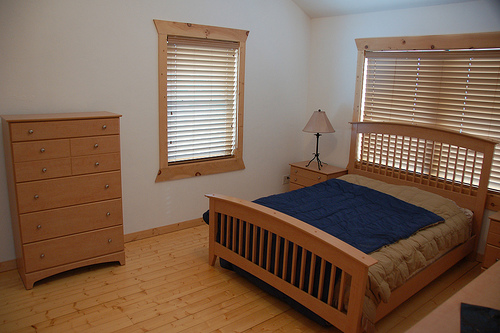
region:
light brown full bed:
[222, 133, 493, 301]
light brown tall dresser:
[16, 96, 139, 278]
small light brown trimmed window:
[150, 15, 247, 180]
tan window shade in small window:
[162, 35, 241, 157]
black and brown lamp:
[302, 103, 337, 180]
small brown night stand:
[271, 163, 350, 191]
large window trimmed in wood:
[350, 34, 496, 204]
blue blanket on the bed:
[232, 172, 442, 285]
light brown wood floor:
[145, 226, 207, 331]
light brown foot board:
[186, 188, 396, 317]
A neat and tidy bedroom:
[1, 1, 499, 331]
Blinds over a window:
[162, 32, 242, 165]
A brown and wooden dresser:
[2, 106, 132, 291]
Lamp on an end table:
[284, 103, 349, 194]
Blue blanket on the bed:
[196, 174, 448, 304]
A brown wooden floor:
[0, 222, 482, 331]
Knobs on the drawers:
[20, 119, 119, 264]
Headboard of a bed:
[343, 114, 498, 216]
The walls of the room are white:
[2, 0, 499, 264]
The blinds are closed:
[162, 31, 499, 198]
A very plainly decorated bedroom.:
[8, 12, 497, 324]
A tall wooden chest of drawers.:
[5, 103, 130, 285]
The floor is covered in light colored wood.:
[13, 175, 494, 331]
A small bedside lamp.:
[298, 98, 336, 172]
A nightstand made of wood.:
[280, 155, 343, 196]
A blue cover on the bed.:
[255, 165, 440, 250]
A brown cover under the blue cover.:
[291, 163, 471, 283]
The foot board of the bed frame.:
[202, 180, 372, 327]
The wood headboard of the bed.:
[346, 112, 496, 215]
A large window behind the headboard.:
[343, 24, 497, 200]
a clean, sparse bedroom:
[6, 4, 485, 324]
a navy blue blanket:
[279, 175, 418, 238]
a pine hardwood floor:
[81, 280, 201, 316]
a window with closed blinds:
[143, 18, 244, 177]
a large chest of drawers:
[7, 103, 137, 263]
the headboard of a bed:
[365, 110, 495, 207]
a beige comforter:
[415, 197, 465, 217]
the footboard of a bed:
[199, 195, 371, 325]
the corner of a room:
[287, 2, 342, 33]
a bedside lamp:
[297, 105, 335, 168]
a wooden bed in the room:
[200, 120, 498, 325]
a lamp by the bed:
[303, 102, 333, 177]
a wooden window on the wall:
[149, 16, 256, 182]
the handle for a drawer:
[98, 122, 108, 132]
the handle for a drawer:
[90, 139, 102, 149]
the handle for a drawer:
[95, 157, 101, 170]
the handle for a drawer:
[104, 184, 113, 191]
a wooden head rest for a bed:
[340, 114, 498, 220]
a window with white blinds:
[162, 32, 242, 163]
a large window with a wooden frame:
[346, 32, 498, 208]